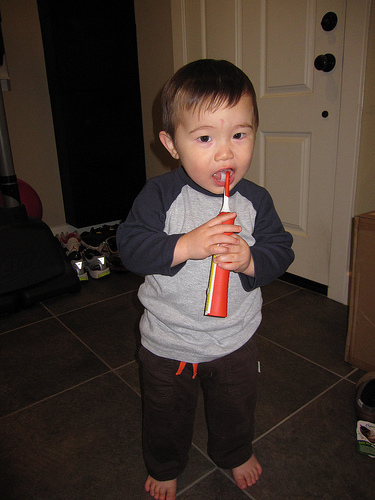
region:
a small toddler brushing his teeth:
[112, 57, 269, 498]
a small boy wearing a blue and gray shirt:
[113, 57, 294, 498]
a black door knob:
[311, 52, 336, 73]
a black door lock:
[320, 12, 337, 30]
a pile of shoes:
[59, 224, 122, 279]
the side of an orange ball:
[16, 178, 43, 218]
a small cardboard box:
[344, 205, 373, 372]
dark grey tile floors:
[0, 274, 373, 499]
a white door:
[169, 2, 366, 307]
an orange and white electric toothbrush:
[203, 171, 230, 317]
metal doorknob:
[308, 48, 341, 78]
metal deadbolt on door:
[313, 6, 343, 36]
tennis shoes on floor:
[57, 223, 115, 279]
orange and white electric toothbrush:
[203, 169, 239, 325]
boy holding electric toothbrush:
[112, 75, 303, 372]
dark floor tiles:
[34, 407, 138, 498]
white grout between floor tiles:
[100, 357, 125, 377]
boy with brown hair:
[154, 53, 271, 200]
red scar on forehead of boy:
[214, 115, 228, 131]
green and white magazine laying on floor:
[353, 418, 373, 468]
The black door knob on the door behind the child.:
[313, 49, 335, 69]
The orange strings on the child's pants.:
[174, 362, 201, 376]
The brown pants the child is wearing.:
[133, 348, 271, 472]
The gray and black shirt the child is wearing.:
[126, 173, 295, 353]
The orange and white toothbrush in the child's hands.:
[207, 163, 231, 316]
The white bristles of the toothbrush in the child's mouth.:
[217, 171, 226, 180]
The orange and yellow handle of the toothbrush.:
[199, 208, 228, 315]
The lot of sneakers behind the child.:
[49, 225, 130, 276]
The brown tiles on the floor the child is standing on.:
[9, 278, 373, 495]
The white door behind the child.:
[170, 5, 348, 295]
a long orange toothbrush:
[202, 168, 242, 321]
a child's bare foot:
[226, 454, 261, 488]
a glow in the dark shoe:
[66, 253, 92, 282]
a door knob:
[312, 47, 337, 74]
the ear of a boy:
[156, 130, 185, 161]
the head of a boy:
[148, 55, 262, 194]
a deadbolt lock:
[318, 12, 336, 30]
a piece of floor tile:
[257, 287, 357, 377]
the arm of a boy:
[114, 174, 245, 274]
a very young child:
[114, 55, 297, 497]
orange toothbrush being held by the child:
[202, 161, 240, 319]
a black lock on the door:
[316, 11, 342, 34]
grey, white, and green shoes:
[66, 252, 112, 279]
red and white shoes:
[61, 229, 90, 250]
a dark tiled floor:
[7, 266, 357, 491]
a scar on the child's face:
[215, 114, 234, 132]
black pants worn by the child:
[133, 351, 271, 465]